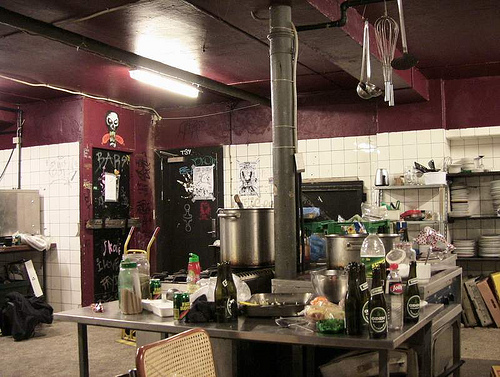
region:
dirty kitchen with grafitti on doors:
[10, 103, 488, 371]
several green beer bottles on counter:
[343, 258, 420, 342]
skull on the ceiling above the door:
[98, 108, 126, 150]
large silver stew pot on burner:
[216, 192, 275, 269]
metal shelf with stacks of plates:
[446, 157, 498, 303]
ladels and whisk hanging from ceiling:
[354, 12, 421, 112]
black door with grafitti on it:
[83, 144, 134, 306]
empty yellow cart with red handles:
[121, 226, 161, 355]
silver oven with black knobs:
[417, 261, 465, 375]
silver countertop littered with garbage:
[51, 275, 436, 375]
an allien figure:
[103, 114, 127, 145]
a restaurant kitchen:
[7, 42, 492, 348]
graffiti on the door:
[90, 149, 138, 171]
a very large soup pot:
[217, 207, 273, 270]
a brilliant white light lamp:
[125, 66, 205, 101]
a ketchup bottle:
[185, 252, 200, 278]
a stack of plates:
[480, 230, 496, 260]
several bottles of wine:
[345, 260, 418, 330]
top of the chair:
[135, 330, 218, 373]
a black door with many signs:
[151, 149, 224, 266]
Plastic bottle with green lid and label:
[358, 225, 388, 287]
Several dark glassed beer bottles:
[345, 258, 427, 338]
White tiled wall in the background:
[0, 142, 79, 192]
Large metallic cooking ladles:
[352, 18, 382, 100]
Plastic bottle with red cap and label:
[385, 263, 405, 332]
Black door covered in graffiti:
[89, 149, 138, 300]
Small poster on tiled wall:
[236, 159, 256, 204]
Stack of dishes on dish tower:
[443, 158, 498, 259]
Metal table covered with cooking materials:
[45, 271, 449, 351]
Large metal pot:
[215, 199, 280, 273]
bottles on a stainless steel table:
[340, 256, 425, 341]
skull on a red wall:
[101, 109, 120, 134]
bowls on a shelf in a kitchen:
[448, 175, 470, 217]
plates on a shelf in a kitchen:
[448, 231, 482, 263]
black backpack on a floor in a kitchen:
[2, 282, 54, 344]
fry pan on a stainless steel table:
[232, 285, 318, 320]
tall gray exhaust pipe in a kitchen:
[262, 48, 304, 282]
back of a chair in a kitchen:
[127, 325, 222, 374]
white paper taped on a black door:
[97, 169, 122, 206]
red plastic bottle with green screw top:
[180, 248, 204, 291]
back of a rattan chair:
[134, 324, 217, 374]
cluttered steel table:
[54, 294, 443, 374]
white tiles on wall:
[223, 127, 498, 234]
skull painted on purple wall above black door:
[82, 96, 152, 301]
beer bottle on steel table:
[368, 267, 391, 339]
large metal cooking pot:
[215, 207, 275, 267]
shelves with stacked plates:
[445, 155, 498, 267]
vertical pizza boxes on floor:
[460, 273, 499, 328]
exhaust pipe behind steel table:
[265, 3, 301, 280]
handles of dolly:
[120, 223, 163, 257]